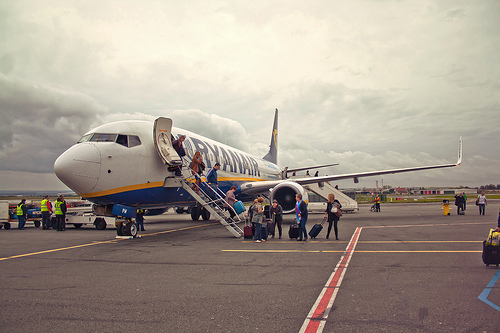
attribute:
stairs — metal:
[176, 164, 243, 242]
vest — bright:
[40, 197, 47, 211]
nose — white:
[53, 142, 101, 195]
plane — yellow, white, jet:
[52, 107, 466, 241]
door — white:
[152, 116, 180, 166]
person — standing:
[324, 192, 341, 240]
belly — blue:
[96, 193, 266, 205]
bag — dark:
[289, 218, 302, 241]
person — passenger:
[222, 185, 237, 217]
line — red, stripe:
[299, 226, 363, 331]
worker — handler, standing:
[14, 198, 28, 229]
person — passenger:
[206, 161, 221, 203]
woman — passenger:
[189, 148, 203, 196]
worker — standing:
[53, 196, 67, 229]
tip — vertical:
[455, 130, 465, 166]